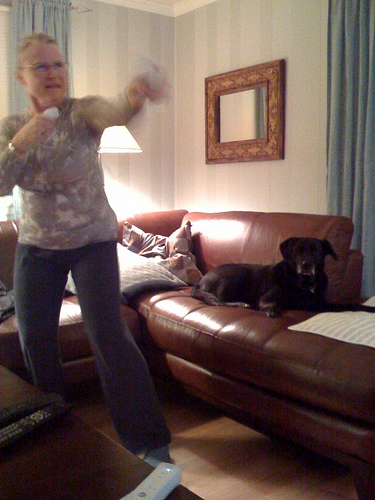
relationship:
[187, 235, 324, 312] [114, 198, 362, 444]
dog sitting couch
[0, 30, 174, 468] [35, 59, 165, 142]
lady playing game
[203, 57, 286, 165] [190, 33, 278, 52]
frame on wall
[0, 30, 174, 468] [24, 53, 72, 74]
lady wearing glasses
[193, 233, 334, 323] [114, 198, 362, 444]
dog on couch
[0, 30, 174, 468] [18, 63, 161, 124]
lady holding remotes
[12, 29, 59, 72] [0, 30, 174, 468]
hair belonging to lady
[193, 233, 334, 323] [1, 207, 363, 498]
dog lying on top of couch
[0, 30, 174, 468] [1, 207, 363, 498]
lady standing next to couch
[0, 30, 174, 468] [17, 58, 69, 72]
lady wearing glasses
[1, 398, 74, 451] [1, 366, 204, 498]
remote lying on top of table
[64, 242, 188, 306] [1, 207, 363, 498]
throw pillow lying on top of couch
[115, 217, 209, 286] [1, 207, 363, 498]
pillow lying on top of couch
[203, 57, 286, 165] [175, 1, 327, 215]
frame hanging on wall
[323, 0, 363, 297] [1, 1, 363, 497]
curtain hanging in living room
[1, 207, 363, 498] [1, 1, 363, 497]
couch sitting inside living room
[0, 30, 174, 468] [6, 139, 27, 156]
lady wearing watch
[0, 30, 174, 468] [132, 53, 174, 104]
lady playing with controller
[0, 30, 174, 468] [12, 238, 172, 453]
lady wearing pants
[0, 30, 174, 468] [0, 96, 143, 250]
lady wearing shirt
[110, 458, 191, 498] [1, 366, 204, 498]
controller lying on top of table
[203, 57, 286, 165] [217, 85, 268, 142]
frame surrounding mirror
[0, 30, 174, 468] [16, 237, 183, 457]
lady wearing pants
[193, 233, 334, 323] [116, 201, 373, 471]
dog laying on a couch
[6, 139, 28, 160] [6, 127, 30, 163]
watch around wrist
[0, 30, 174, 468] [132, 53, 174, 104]
lady holding controller